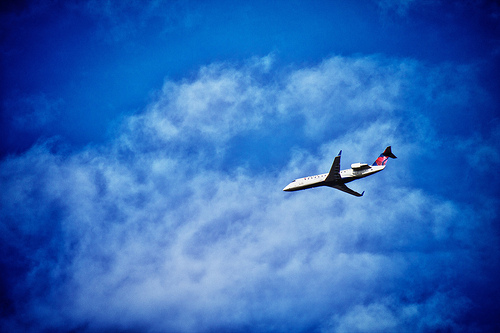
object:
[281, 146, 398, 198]
airplane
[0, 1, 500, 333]
sky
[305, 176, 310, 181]
window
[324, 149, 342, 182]
wing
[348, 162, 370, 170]
engine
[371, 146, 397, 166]
tail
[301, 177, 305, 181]
window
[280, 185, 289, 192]
nose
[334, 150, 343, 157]
tip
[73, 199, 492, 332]
clouds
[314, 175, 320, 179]
window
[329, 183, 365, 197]
wing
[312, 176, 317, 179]
window